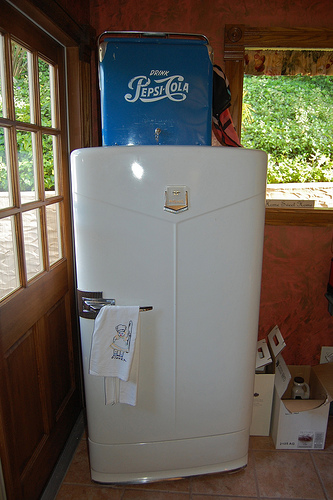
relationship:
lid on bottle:
[294, 376, 304, 383] [289, 373, 311, 399]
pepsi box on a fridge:
[97, 30, 214, 147] [70, 144, 267, 483]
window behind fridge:
[250, 67, 331, 196] [81, 142, 311, 476]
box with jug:
[270, 354, 333, 450] [292, 374, 308, 400]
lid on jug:
[295, 377, 302, 382] [292, 374, 308, 400]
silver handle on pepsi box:
[99, 29, 203, 37] [97, 30, 214, 147]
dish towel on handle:
[88, 305, 140, 407] [85, 292, 158, 317]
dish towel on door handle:
[88, 305, 140, 407] [77, 290, 150, 317]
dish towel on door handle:
[88, 305, 140, 407] [77, 288, 160, 319]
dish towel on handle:
[88, 305, 140, 407] [80, 285, 155, 324]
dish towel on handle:
[88, 305, 140, 407] [78, 290, 152, 320]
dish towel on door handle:
[88, 305, 140, 407] [86, 304, 102, 313]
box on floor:
[249, 326, 286, 436] [0, 449, 330, 498]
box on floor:
[249, 336, 277, 436] [53, 368, 332, 498]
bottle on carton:
[292, 376, 309, 398] [270, 352, 331, 449]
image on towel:
[105, 317, 135, 364] [88, 301, 140, 408]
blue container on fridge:
[90, 30, 218, 145] [70, 144, 267, 483]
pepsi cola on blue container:
[123, 74, 189, 103] [98, 31, 212, 148]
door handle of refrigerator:
[83, 297, 153, 319] [70, 145, 273, 480]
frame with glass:
[2, 1, 72, 320] [10, 36, 38, 123]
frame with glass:
[2, 1, 72, 320] [34, 53, 55, 126]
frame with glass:
[2, 1, 72, 320] [13, 124, 40, 205]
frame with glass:
[2, 1, 72, 320] [37, 132, 63, 199]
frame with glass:
[2, 1, 72, 320] [14, 209, 49, 285]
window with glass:
[1, 33, 65, 301] [10, 36, 38, 123]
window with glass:
[1, 33, 65, 301] [34, 53, 55, 126]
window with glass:
[1, 33, 65, 301] [13, 124, 40, 205]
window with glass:
[1, 33, 65, 301] [37, 132, 63, 199]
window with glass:
[1, 33, 65, 301] [14, 209, 49, 285]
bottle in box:
[292, 376, 310, 399] [276, 367, 326, 452]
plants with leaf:
[275, 87, 323, 177] [300, 114, 304, 121]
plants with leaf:
[275, 87, 323, 177] [280, 133, 288, 139]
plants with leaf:
[275, 87, 323, 177] [273, 92, 285, 101]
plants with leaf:
[275, 87, 323, 177] [257, 120, 265, 125]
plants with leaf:
[275, 87, 323, 177] [272, 84, 281, 91]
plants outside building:
[275, 87, 323, 177] [1, 0, 331, 495]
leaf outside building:
[300, 114, 304, 121] [1, 0, 331, 495]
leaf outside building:
[280, 133, 288, 139] [1, 0, 331, 495]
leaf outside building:
[257, 120, 265, 125] [1, 0, 331, 495]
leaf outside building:
[273, 92, 285, 101] [1, 0, 331, 495]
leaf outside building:
[272, 84, 281, 91] [1, 0, 331, 495]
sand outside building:
[2, 181, 332, 299] [4, 3, 329, 329]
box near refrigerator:
[270, 354, 333, 450] [76, 147, 260, 483]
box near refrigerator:
[249, 326, 286, 436] [76, 147, 260, 483]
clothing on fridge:
[212, 64, 242, 147] [70, 144, 267, 483]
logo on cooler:
[116, 65, 213, 133] [96, 29, 212, 147]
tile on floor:
[244, 442, 326, 496] [9, 399, 332, 498]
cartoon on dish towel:
[110, 321, 134, 365] [86, 303, 147, 408]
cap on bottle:
[291, 374, 308, 386] [287, 374, 314, 402]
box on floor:
[266, 327, 331, 449] [0, 389, 331, 497]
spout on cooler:
[152, 127, 160, 141] [96, 29, 212, 147]